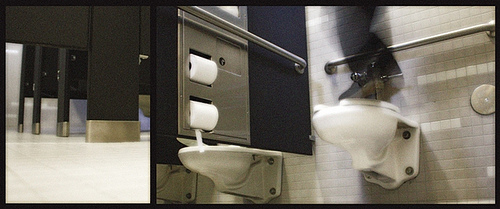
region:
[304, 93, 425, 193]
white toilet attached to wall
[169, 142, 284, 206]
white toilet attached to wall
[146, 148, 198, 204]
white toilet attached to wall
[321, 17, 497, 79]
silver metal handlebar attached to wall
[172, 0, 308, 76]
silver metal handlebar attached to wall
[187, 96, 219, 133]
white toilet paper roll in bathroom stall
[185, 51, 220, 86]
white toilet paper roll in bathroom stall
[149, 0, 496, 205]
gray and white tiled bathroom wall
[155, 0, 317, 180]
black bathroom stall wall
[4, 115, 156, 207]
tiled white bathroom floor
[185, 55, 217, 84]
a roll of toilet paper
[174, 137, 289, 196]
a toilet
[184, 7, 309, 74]
a handle bar next to the toilet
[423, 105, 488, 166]
grey and white tiles on the background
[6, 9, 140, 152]
the bathroom stalls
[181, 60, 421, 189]
two toilets in a bathroom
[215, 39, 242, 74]
a trash basket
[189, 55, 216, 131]
two rolls of toilet paper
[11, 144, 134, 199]
white tile on the floor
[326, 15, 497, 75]
a handle on the back of the toilet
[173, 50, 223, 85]
white roll of toilet paper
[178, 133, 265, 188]
toilet under paper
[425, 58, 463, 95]
white and gray wall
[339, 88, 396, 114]
lid of the toilet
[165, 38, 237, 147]
two rolls of toilet paper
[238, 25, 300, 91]
pole next to toilet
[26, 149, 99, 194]
tile in room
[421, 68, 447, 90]
white squares on wall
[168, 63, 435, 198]
two toilets in photo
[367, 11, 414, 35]
shadow above the toilet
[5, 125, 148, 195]
white floor of public bathroom with stalls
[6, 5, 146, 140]
black panels and silver hardware on supports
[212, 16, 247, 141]
side of silver panel for garbage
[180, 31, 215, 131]
rolls of white toilet paper in metal panel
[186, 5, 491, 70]
silver grab bars on walls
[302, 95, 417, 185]
curved bowl of white toilet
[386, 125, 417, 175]
flat panel with bolts through wall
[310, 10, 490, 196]
gray tiles with short white stripes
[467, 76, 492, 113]
metal lid with white button in center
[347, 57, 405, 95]
silver lever and pipes for toilet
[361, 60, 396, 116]
part of a metal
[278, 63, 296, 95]
part of a wall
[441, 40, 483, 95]
aprt of a wall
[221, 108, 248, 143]
part of a mirror